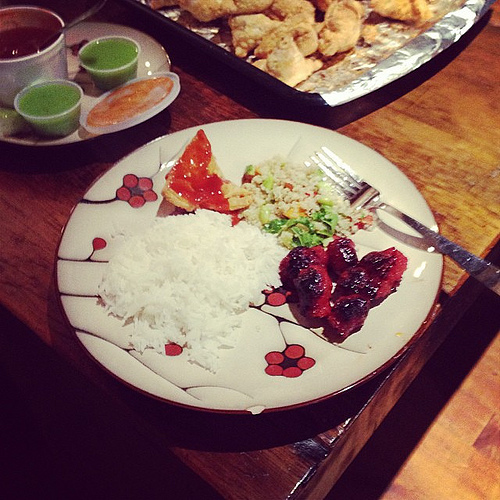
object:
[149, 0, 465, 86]
food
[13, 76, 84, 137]
container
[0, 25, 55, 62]
sauce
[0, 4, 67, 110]
container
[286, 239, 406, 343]
meat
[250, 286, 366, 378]
plate print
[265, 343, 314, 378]
flower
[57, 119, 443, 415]
plate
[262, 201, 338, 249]
lettuce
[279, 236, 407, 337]
meat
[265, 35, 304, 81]
pizza roll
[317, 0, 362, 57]
pizza roll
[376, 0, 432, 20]
pizza roll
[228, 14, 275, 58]
pizza roll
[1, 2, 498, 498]
table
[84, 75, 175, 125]
sauce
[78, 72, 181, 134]
lid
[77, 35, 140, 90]
container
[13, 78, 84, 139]
cup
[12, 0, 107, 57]
spoon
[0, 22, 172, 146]
plate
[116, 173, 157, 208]
rose design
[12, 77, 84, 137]
guacamole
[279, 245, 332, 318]
glaze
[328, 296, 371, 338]
glaze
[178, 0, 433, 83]
wontons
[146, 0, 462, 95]
pan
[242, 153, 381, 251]
vegetables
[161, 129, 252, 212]
fried wonton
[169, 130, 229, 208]
sauce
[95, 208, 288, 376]
rice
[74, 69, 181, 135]
top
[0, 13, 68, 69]
sauce's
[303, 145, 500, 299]
fork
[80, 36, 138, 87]
cup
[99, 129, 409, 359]
food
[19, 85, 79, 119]
liquid